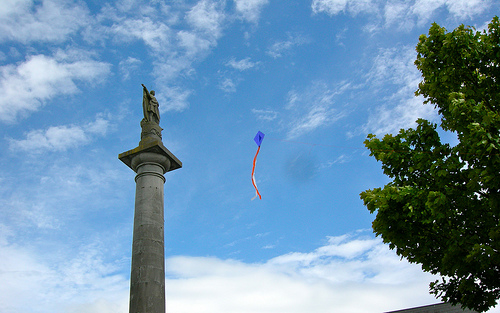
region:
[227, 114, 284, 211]
kite flown in mid air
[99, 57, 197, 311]
a tall statue manument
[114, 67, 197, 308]
a stone tall manument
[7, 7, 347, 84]
clouds in the sky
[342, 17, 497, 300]
a tall tree with branches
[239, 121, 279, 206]
a blue kite with red tails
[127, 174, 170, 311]
a tall stone pillar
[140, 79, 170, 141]
a stone figure on top of pillar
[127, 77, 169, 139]
a stone figure making body gesture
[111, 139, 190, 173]
base of the stone pillar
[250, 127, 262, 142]
blue kite flying beside of statue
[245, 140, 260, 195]
orange and white tail of kite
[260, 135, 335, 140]
string of kite flying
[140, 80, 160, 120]
concrete statue of person with arm out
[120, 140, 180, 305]
grey concrete pole of statue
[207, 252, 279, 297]
white clouds in the distance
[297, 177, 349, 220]
blue sky in the distance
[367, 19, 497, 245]
green tree beside large statue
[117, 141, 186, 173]
grey concrete platform for statue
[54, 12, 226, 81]
party cloudy sky over statue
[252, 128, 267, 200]
a red white and blue kite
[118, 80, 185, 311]
a very tall grey statue on a pillar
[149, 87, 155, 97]
the head of a grey statue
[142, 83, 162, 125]
a tall stone statue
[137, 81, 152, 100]
the arm of a statue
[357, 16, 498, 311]
a very leafy green tree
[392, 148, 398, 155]
the green leaf of a tree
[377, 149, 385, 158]
the green leaf of a tree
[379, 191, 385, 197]
the green leaf of a tree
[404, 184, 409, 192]
the green leaf of a tree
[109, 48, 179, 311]
gray tall tower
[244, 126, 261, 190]
kite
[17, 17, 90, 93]
white clouds in blue sky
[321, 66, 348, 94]
white clouds in blue sky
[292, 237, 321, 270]
white clouds in blue sky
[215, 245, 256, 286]
white clouds in blue sky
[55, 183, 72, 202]
white clouds in blue sky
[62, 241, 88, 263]
white clouds in blue sky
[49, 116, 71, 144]
white clouds in blue sky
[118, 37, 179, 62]
white clouds in blue sky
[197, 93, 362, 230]
a kite in the air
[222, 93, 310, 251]
a kite in the sky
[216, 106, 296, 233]
a kite flying in the air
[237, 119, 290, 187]
a kite flying in the sky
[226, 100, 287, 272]
a kite that is blue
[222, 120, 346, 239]
a blue kite in the air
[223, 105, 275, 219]
a blue kite in the sky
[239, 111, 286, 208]
a kite with a long tail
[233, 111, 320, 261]
a blue kite with long tail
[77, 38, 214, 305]
a tall statue